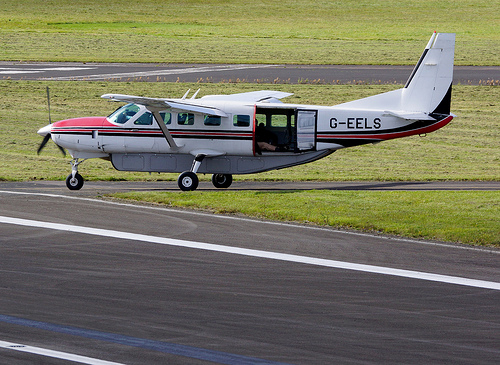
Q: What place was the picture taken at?
A: It was taken at the field.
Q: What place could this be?
A: It is a field.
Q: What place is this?
A: It is a field.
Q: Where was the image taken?
A: It was taken at the field.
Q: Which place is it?
A: It is a field.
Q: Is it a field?
A: Yes, it is a field.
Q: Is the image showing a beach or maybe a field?
A: It is showing a field.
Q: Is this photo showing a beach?
A: No, the picture is showing a field.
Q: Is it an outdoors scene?
A: Yes, it is outdoors.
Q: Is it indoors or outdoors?
A: It is outdoors.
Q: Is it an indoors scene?
A: No, it is outdoors.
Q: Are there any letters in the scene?
A: Yes, there are letters.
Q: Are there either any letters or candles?
A: Yes, there are letters.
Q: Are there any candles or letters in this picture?
A: Yes, there are letters.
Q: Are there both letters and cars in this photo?
A: No, there are letters but no cars.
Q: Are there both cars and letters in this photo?
A: No, there are letters but no cars.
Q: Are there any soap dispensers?
A: No, there are no soap dispensers.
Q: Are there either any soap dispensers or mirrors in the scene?
A: No, there are no soap dispensers or mirrors.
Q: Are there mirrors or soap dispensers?
A: No, there are no soap dispensers or mirrors.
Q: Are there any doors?
A: Yes, there is a door.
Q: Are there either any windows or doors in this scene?
A: Yes, there is a door.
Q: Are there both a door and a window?
A: Yes, there are both a door and a window.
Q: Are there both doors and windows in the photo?
A: Yes, there are both a door and a window.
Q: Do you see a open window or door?
A: Yes, there is an open door.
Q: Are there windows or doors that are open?
A: Yes, the door is open.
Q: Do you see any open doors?
A: Yes, there is an open door.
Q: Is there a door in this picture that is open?
A: Yes, there is a door that is open.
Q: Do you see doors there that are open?
A: Yes, there is a door that is open.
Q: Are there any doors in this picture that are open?
A: Yes, there is a door that is open.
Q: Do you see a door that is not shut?
A: Yes, there is a open door.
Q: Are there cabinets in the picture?
A: No, there are no cabinets.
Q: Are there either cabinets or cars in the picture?
A: No, there are no cabinets or cars.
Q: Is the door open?
A: Yes, the door is open.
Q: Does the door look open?
A: Yes, the door is open.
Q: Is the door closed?
A: No, the door is open.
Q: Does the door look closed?
A: No, the door is open.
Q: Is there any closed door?
A: No, there is a door but it is open.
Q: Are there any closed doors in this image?
A: No, there is a door but it is open.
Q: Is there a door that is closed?
A: No, there is a door but it is open.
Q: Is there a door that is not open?
A: No, there is a door but it is open.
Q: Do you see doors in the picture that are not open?
A: No, there is a door but it is open.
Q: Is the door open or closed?
A: The door is open.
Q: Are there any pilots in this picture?
A: No, there are no pilots.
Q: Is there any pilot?
A: No, there are no pilots.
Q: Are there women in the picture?
A: No, there are no women.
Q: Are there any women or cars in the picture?
A: No, there are no women or cars.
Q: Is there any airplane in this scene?
A: Yes, there is an airplane.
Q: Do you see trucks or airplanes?
A: Yes, there is an airplane.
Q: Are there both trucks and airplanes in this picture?
A: No, there is an airplane but no trucks.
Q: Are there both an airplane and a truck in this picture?
A: No, there is an airplane but no trucks.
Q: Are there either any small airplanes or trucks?
A: Yes, there is a small airplane.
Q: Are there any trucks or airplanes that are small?
A: Yes, the airplane is small.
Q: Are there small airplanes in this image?
A: Yes, there is a small airplane.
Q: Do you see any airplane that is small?
A: Yes, there is an airplane that is small.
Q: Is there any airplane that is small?
A: Yes, there is an airplane that is small.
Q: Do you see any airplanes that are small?
A: Yes, there is an airplane that is small.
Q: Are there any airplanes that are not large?
A: Yes, there is a small airplane.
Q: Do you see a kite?
A: No, there are no kites.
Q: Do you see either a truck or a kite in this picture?
A: No, there are no kites or trucks.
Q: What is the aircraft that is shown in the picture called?
A: The aircraft is an airplane.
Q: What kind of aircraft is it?
A: The aircraft is an airplane.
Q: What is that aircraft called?
A: This is an airplane.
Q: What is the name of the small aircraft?
A: The aircraft is an airplane.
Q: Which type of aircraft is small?
A: The aircraft is an airplane.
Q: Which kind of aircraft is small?
A: The aircraft is an airplane.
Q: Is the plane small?
A: Yes, the plane is small.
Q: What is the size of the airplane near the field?
A: The airplane is small.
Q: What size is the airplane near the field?
A: The airplane is small.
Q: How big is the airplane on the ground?
A: The plane is small.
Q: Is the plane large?
A: No, the plane is small.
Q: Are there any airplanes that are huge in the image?
A: No, there is an airplane but it is small.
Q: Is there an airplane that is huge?
A: No, there is an airplane but it is small.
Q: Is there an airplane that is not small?
A: No, there is an airplane but it is small.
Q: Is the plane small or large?
A: The plane is small.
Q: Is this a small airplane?
A: Yes, this is a small airplane.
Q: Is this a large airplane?
A: No, this is a small airplane.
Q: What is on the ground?
A: The airplane is on the ground.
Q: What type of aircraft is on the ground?
A: The aircraft is an airplane.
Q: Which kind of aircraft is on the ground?
A: The aircraft is an airplane.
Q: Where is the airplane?
A: The airplane is on the ground.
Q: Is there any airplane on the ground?
A: Yes, there is an airplane on the ground.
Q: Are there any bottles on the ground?
A: No, there is an airplane on the ground.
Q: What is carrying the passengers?
A: The plane is carrying the passengers.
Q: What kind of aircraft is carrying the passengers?
A: The aircraft is an airplane.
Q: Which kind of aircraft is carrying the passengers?
A: The aircraft is an airplane.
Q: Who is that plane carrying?
A: The plane is carrying passengers.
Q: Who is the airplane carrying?
A: The plane is carrying passengers.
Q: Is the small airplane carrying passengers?
A: Yes, the airplane is carrying passengers.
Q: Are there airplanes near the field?
A: Yes, there is an airplane near the field.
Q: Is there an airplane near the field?
A: Yes, there is an airplane near the field.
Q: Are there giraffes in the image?
A: No, there are no giraffes.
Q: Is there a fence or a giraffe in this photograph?
A: No, there are no giraffes or fences.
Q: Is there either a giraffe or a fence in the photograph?
A: No, there are no giraffes or fences.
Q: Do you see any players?
A: No, there are no players.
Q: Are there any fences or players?
A: No, there are no players or fences.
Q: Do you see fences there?
A: No, there are no fences.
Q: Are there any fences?
A: No, there are no fences.